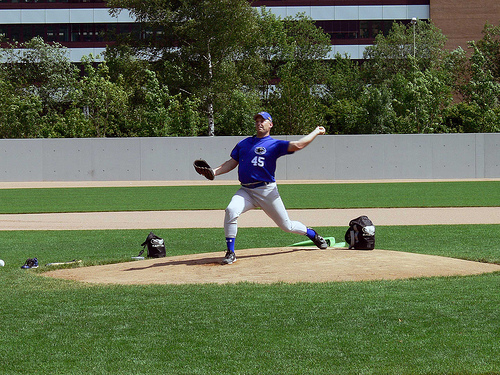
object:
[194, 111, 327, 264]
player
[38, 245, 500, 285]
mound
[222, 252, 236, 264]
shoe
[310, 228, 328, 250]
shoe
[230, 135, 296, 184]
jersey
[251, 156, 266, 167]
number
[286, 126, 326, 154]
arm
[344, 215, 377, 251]
bag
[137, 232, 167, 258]
bag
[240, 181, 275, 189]
belt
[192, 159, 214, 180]
mitt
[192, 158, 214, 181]
hand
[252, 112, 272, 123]
hat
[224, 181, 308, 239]
pants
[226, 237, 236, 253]
sock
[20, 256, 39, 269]
shoe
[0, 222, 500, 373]
grass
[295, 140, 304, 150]
elbow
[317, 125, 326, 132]
ball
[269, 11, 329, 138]
tree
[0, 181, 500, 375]
field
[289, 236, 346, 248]
plate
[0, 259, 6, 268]
ball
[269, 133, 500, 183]
wall